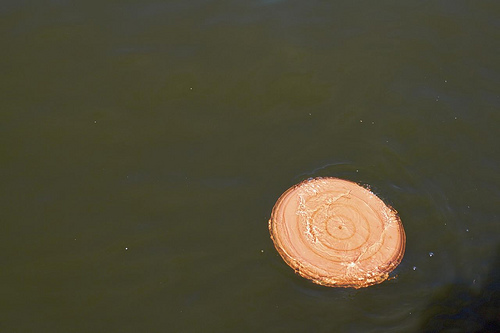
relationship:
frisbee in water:
[270, 176, 405, 286] [1, 1, 498, 331]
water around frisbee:
[1, 1, 498, 331] [270, 176, 405, 286]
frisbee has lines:
[270, 176, 405, 286] [304, 200, 381, 257]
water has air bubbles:
[1, 1, 498, 331] [412, 226, 473, 273]